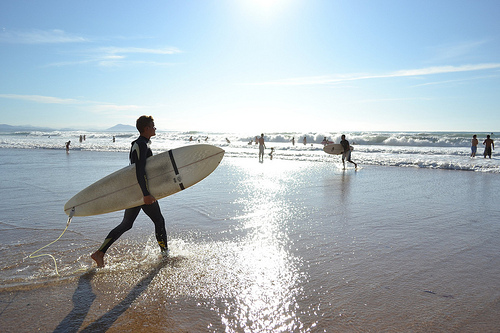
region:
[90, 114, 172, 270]
A dark haired man walking towards the right with a white surfboard.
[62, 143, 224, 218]
Closest white surfboard.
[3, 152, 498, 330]
All the immediate shallow water.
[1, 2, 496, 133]
A blue and white sky.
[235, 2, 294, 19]
Where the sun is shining down in the sky.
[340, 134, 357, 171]
Man running to the left with a surfboard.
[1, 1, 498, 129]
A mostly blue sky.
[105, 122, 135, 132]
Tallest hill in the distance.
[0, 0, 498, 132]
A blue sky with clouds.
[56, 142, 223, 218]
White surfboard with black strip across it.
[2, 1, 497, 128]
sunshine in blue sky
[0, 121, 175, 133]
hazy mountains on horizon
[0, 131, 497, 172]
crashing waves of ocean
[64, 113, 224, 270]
man walking with surfboard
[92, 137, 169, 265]
wetsuit on man's body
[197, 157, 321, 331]
light reflection on water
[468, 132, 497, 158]
people standing in water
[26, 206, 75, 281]
white cord on surfboard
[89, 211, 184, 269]
feet walking in splashed water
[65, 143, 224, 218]
arm in wetsuit over surfboard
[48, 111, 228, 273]
man carrying white surfboard on beach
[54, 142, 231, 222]
long white surfboard with black stripe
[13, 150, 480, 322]
watery beach sand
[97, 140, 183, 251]
man wearing blue wetsuit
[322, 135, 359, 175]
man carrying white surboard on beach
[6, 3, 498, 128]
bright blue sky with white clouds and sun shining though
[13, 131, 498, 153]
white waves in blue ocean water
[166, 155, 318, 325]
sun reflected in water on shore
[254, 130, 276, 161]
man with child on beach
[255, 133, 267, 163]
shirtless man in white shorts on beach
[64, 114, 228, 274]
Man carrying a white surfboard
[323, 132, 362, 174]
Man carrying a white surfboard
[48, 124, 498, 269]
People enjoying the water and the beach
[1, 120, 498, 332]
The surf is coming in